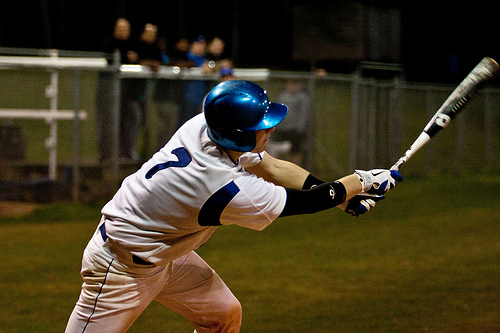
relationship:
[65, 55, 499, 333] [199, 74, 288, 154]
batter wearing a helmet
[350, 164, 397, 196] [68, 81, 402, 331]
glove of man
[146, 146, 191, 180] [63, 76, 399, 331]
blue seven on shirt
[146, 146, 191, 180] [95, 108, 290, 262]
blue seven on jersey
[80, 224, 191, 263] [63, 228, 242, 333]
belt on man's pants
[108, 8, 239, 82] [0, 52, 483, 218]
fans leaning on fence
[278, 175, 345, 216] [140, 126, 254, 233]
sleeves under jersey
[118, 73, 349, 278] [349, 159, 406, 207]
batter wearing gloves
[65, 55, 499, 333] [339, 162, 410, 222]
batter wearing gloves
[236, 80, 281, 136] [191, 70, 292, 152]
light in helmet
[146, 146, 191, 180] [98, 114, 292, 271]
blue seven in jersey